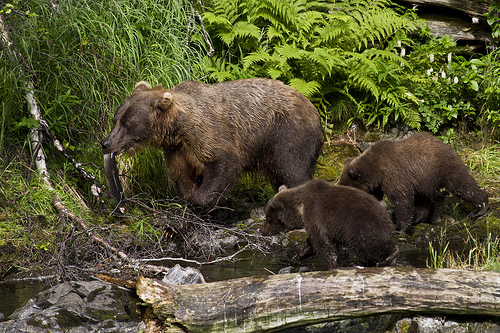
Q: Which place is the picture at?
A: It is at the river.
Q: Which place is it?
A: It is a river.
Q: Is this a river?
A: Yes, it is a river.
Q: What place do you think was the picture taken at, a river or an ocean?
A: It was taken at a river.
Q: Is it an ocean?
A: No, it is a river.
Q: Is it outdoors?
A: Yes, it is outdoors.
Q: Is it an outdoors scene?
A: Yes, it is outdoors.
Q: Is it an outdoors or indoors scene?
A: It is outdoors.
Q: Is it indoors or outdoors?
A: It is outdoors.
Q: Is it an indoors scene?
A: No, it is outdoors.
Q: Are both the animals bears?
A: Yes, all the animals are bears.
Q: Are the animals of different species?
A: No, all the animals are bears.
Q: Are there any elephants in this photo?
A: No, there are no elephants.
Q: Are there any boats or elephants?
A: No, there are no elephants or boats.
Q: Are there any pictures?
A: No, there are no pictures.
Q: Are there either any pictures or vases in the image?
A: No, there are no pictures or vases.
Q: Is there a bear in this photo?
A: Yes, there is a bear.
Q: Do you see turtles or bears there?
A: Yes, there is a bear.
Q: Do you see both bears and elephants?
A: No, there is a bear but no elephants.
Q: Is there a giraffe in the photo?
A: No, there are no giraffes.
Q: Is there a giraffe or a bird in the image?
A: No, there are no giraffes or birds.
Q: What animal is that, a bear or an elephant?
A: That is a bear.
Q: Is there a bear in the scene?
A: Yes, there is a bear.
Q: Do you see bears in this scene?
A: Yes, there is a bear.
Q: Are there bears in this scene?
A: Yes, there is a bear.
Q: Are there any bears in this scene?
A: Yes, there is a bear.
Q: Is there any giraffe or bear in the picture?
A: Yes, there is a bear.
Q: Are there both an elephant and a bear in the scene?
A: No, there is a bear but no elephants.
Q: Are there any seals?
A: No, there are no seals.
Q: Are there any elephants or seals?
A: No, there are no seals or elephants.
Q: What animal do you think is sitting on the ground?
A: The animal is a bear.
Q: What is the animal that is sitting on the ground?
A: The animal is a bear.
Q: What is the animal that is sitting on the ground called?
A: The animal is a bear.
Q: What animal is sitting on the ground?
A: The animal is a bear.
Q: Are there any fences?
A: No, there are no fences.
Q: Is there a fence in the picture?
A: No, there are no fences.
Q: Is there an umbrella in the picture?
A: No, there are no umbrellas.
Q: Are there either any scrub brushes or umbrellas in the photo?
A: No, there are no umbrellas or scrub brushes.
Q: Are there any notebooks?
A: No, there are no notebooks.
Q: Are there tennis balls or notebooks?
A: No, there are no notebooks or tennis balls.